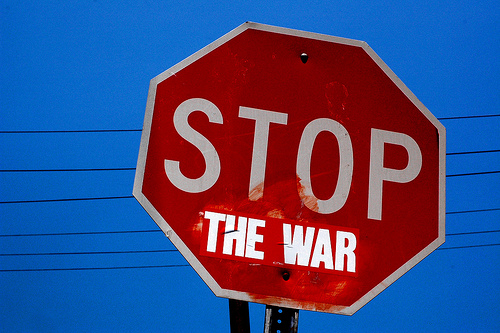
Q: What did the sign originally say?
A: STOP.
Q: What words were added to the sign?
A: THE WAR.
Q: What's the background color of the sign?
A: Red.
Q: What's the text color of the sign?
A: White.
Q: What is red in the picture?
A: Sign.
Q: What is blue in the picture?
A: Sky.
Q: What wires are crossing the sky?
A: Electrical.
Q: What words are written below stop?
A: The war.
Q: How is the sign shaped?
A: Octagonally.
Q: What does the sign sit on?
A: A pole.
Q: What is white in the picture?
A: Words.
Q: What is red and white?
A: The stop sign.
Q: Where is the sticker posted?
A: On the stop sign.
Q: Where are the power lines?
A: Behind the stop sign.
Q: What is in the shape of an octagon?
A: The stop sign.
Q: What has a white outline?
A: The stop sign.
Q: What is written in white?
A: STOP.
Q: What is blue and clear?
A: The sky.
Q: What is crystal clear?
A: The sky.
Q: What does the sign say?
A: Stop the war.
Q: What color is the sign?
A: Red and white.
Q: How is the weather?
A: Clear and sunny.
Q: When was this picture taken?
A: Daytime.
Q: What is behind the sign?
A: Power lines.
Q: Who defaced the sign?
A: A person who wants the war to stop.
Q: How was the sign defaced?
A: Red paint and a bumper sticker.